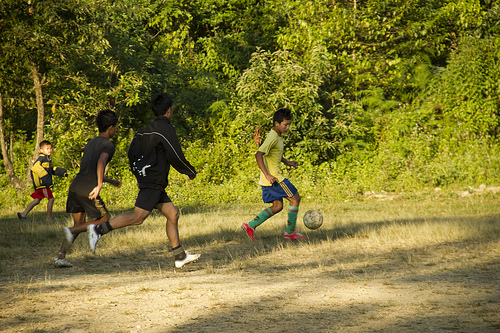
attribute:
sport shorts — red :
[23, 182, 58, 206]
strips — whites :
[41, 189, 48, 198]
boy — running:
[86, 91, 202, 267]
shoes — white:
[83, 221, 227, 271]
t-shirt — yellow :
[256, 130, 291, 182]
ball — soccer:
[297, 192, 332, 242]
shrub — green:
[210, 45, 332, 171]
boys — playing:
[28, 100, 310, 258]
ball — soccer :
[303, 209, 325, 230]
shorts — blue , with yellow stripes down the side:
[257, 183, 307, 204]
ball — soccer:
[295, 197, 345, 252]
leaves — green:
[299, 55, 347, 92]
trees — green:
[189, 9, 412, 114]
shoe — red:
[238, 221, 261, 248]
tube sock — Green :
[285, 204, 305, 231]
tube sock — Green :
[246, 204, 273, 229]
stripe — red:
[287, 208, 299, 218]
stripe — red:
[262, 204, 273, 220]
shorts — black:
[64, 186, 123, 233]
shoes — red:
[228, 209, 316, 246]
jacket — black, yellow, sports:
[29, 154, 65, 185]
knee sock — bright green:
[287, 205, 302, 234]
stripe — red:
[284, 210, 300, 215]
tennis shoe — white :
[165, 247, 203, 269]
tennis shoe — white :
[84, 221, 101, 251]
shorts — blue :
[260, 176, 300, 203]